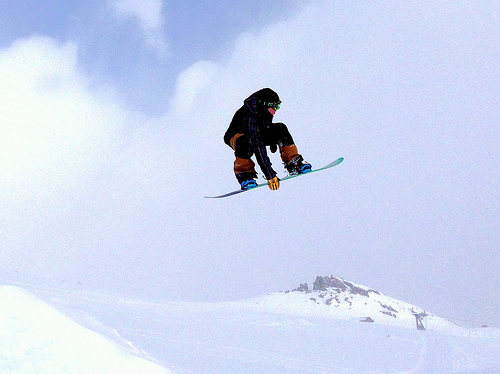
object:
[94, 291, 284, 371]
snow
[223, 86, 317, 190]
man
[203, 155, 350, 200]
snowboard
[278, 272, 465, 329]
mountain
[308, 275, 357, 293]
tip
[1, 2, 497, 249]
sky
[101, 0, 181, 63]
clouds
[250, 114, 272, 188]
strip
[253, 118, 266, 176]
arm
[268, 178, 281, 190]
glove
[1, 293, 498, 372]
tracks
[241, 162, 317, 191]
boots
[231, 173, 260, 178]
socks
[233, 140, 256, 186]
leg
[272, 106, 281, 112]
goggles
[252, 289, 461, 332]
snow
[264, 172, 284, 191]
hand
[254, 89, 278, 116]
head